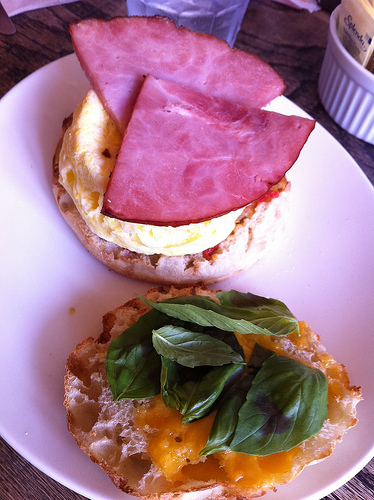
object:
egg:
[54, 89, 245, 254]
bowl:
[318, 0, 374, 143]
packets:
[333, 0, 373, 68]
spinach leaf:
[103, 308, 167, 400]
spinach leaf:
[158, 371, 231, 425]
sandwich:
[51, 10, 316, 288]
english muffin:
[47, 17, 316, 290]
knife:
[0, 0, 16, 36]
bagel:
[62, 283, 362, 498]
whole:
[116, 449, 152, 488]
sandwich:
[63, 284, 362, 497]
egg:
[61, 88, 248, 256]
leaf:
[133, 283, 300, 340]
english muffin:
[63, 281, 364, 498]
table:
[0, 0, 374, 500]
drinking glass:
[123, 1, 249, 48]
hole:
[73, 403, 96, 427]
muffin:
[62, 290, 356, 496]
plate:
[0, 49, 373, 497]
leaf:
[105, 301, 195, 406]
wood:
[0, 4, 74, 80]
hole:
[67, 348, 103, 387]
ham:
[68, 16, 288, 132]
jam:
[132, 391, 213, 476]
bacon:
[100, 71, 322, 227]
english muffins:
[58, 68, 317, 492]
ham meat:
[102, 69, 317, 226]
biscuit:
[49, 90, 291, 287]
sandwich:
[49, 15, 311, 284]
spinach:
[105, 289, 329, 456]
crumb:
[26, 424, 38, 443]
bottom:
[57, 69, 263, 263]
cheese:
[127, 314, 326, 496]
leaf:
[223, 356, 329, 455]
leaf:
[150, 324, 248, 370]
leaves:
[105, 284, 215, 405]